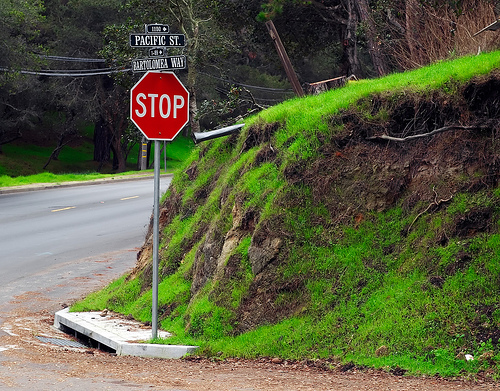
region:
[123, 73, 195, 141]
red and white sign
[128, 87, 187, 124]
stop in white letters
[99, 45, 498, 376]
hills with green moss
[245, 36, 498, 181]
radiant green moss on hill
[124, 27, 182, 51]
pacific st on the sign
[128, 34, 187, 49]
black and white sign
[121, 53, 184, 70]
black and white sign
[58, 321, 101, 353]
water whole under curb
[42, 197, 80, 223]
yellow line on street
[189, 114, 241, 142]
water drainage pipe on hill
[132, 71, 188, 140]
the stop sign on the curb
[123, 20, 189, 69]
the black signs on the pole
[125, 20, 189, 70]
the road signs above the stop sign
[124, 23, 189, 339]
the street signs in the pole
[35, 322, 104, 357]
the grate and drain on the ground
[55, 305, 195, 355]
the curb on the side of the road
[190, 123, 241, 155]
the pipe coimng out of the grass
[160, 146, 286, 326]
the grass on the hillside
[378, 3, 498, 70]
the branches on the hilltop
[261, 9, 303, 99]
the post on the hill leaning over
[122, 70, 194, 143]
a red and white stop sign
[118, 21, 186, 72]
black and white street signs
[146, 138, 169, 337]
the post holding up street signs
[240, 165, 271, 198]
a patch of green mold on a hillside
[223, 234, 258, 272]
a patch of green mold on a hillside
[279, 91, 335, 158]
a patch of green mold on a hillside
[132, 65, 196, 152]
red stop sign on post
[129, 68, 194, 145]
eight sided stop sign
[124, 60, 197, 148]
eight sided red sign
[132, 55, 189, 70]
name of street on sign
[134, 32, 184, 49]
name of street of sign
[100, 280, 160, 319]
green grass on hill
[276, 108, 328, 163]
green grass on hill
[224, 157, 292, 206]
green grass on hill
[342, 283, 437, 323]
green grass on hill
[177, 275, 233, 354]
green grass on hill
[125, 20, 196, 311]
stop sign on a street corner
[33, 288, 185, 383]
gutter on the side of a road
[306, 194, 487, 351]
moss growing on a bank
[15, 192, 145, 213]
yellow lines on a road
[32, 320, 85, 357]
grate in the gutter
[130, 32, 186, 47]
a pacific street sign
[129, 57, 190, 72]
this sign is hard to read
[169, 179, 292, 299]
rocks and moss on a hill side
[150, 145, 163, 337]
street sign poll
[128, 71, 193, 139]
top of a street sign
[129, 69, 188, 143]
the stop sign is red and white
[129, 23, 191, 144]
the street signs above the stop sign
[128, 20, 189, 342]
the signs on the pole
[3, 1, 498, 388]
the greenery next to the road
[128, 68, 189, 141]
the stop sign shaped like an octagon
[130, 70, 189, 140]
the white letters on the sign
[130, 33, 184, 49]
the white letters on the street sign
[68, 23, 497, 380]
the green grass next to the street signs